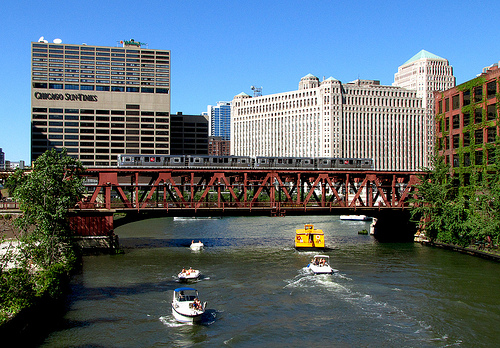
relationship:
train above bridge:
[112, 146, 383, 182] [76, 152, 427, 224]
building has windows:
[214, 79, 455, 185] [235, 87, 423, 173]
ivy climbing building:
[411, 74, 499, 246] [429, 61, 499, 231]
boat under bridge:
[296, 222, 326, 250] [53, 168, 436, 265]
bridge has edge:
[41, 145, 451, 253] [208, 159, 274, 176]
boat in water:
[295, 224, 325, 247] [110, 217, 380, 328]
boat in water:
[307, 255, 334, 276] [31, 216, 498, 346]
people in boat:
[181, 266, 195, 277] [177, 265, 201, 284]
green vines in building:
[443, 160, 486, 210] [419, 78, 498, 239]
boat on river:
[306, 253, 331, 275] [1, 211, 498, 346]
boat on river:
[190, 239, 205, 251] [1, 211, 498, 346]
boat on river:
[167, 282, 205, 324] [1, 211, 498, 346]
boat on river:
[177, 265, 201, 284] [1, 211, 498, 346]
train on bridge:
[112, 146, 383, 182] [114, 148, 378, 172]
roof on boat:
[165, 261, 211, 285] [160, 280, 209, 338]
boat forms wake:
[307, 255, 334, 276] [291, 267, 351, 292]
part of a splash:
[310, 270, 320, 284] [300, 268, 356, 298]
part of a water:
[269, 322, 351, 342] [226, 237, 302, 319]